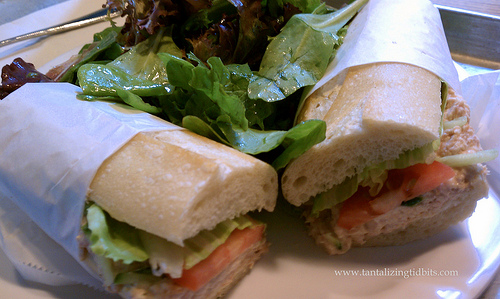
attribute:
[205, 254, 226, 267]
tomato — slice, here, sliced, red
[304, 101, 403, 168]
bread — white, piece, here, brown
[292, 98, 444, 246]
sandwich — wrapped, part, cut, half, here, baguette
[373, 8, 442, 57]
paper — white, piece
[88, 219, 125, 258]
lettuce — here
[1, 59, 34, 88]
leaf — shiny, purple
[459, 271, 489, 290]
plate — here, white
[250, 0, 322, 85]
leaves — green, red, purple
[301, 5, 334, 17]
spinach — piece, green